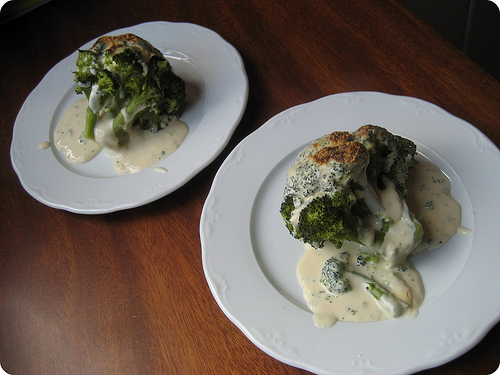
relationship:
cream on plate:
[412, 162, 462, 244] [203, 184, 283, 345]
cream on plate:
[412, 162, 462, 244] [189, 22, 244, 124]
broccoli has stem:
[284, 132, 390, 249] [354, 184, 424, 276]